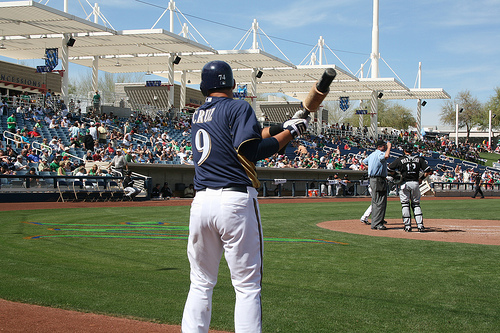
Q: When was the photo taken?
A: Daytime.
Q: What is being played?
A: Baseball.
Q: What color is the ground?
A: Green.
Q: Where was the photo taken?
A: In ball park.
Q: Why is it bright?
A: Sunny.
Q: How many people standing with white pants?
A: Three.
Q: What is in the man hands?
A: A bat.